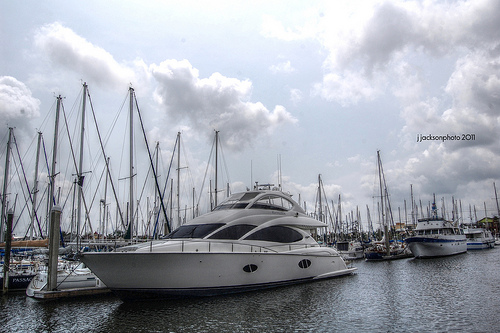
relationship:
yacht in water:
[73, 187, 357, 315] [258, 287, 479, 331]